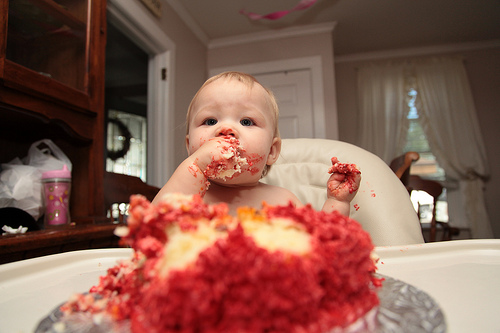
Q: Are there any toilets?
A: No, there are no toilets.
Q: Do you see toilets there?
A: No, there are no toilets.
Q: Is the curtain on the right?
A: Yes, the curtain is on the right of the image.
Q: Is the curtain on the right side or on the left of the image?
A: The curtain is on the right of the image.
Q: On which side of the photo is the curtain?
A: The curtain is on the right of the image.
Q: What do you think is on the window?
A: The curtain is on the window.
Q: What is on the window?
A: The curtain is on the window.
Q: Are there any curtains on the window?
A: Yes, there is a curtain on the window.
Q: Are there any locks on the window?
A: No, there is a curtain on the window.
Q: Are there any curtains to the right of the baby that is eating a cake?
A: Yes, there is a curtain to the right of the baby.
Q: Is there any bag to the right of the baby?
A: No, there is a curtain to the right of the baby.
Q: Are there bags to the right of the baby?
A: No, there is a curtain to the right of the baby.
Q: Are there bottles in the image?
A: Yes, there is a bottle.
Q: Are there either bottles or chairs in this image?
A: Yes, there is a bottle.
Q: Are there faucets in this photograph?
A: No, there are no faucets.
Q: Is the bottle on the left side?
A: Yes, the bottle is on the left of the image.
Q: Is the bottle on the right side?
A: No, the bottle is on the left of the image.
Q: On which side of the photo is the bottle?
A: The bottle is on the left of the image.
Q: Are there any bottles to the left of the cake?
A: Yes, there is a bottle to the left of the cake.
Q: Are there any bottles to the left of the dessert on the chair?
A: Yes, there is a bottle to the left of the cake.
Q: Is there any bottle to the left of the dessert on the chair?
A: Yes, there is a bottle to the left of the cake.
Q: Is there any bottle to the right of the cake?
A: No, the bottle is to the left of the cake.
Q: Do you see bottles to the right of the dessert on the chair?
A: No, the bottle is to the left of the cake.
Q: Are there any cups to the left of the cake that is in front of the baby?
A: No, there is a bottle to the left of the cake.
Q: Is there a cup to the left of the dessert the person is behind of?
A: No, there is a bottle to the left of the cake.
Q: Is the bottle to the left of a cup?
A: No, the bottle is to the left of the cake.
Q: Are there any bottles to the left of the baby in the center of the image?
A: Yes, there is a bottle to the left of the baby.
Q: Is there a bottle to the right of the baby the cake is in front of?
A: No, the bottle is to the left of the baby.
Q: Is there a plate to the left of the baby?
A: No, there is a bottle to the left of the baby.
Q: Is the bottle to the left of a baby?
A: Yes, the bottle is to the left of a baby.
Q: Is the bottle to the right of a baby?
A: No, the bottle is to the left of a baby.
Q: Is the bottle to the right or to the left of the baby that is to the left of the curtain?
A: The bottle is to the left of the baby.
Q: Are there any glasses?
A: No, there are no glasses.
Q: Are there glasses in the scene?
A: No, there are no glasses.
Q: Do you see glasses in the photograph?
A: No, there are no glasses.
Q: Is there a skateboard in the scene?
A: No, there are no skateboards.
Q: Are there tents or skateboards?
A: No, there are no skateboards or tents.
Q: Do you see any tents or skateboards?
A: No, there are no skateboards or tents.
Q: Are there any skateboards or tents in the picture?
A: No, there are no skateboards or tents.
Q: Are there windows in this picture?
A: Yes, there is a window.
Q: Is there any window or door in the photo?
A: Yes, there is a window.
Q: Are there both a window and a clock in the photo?
A: No, there is a window but no clocks.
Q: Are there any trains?
A: No, there are no trains.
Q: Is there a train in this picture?
A: No, there are no trains.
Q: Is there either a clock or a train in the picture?
A: No, there are no trains or clocks.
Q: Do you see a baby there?
A: Yes, there is a baby.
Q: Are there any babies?
A: Yes, there is a baby.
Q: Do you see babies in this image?
A: Yes, there is a baby.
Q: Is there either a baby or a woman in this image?
A: Yes, there is a baby.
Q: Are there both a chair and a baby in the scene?
A: Yes, there are both a baby and a chair.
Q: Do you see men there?
A: No, there are no men.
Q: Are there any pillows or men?
A: No, there are no men or pillows.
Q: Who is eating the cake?
A: The baby is eating the cake.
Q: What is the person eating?
A: The baby is eating a cake.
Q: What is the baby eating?
A: The baby is eating a cake.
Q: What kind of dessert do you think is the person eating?
A: The baby is eating a cake.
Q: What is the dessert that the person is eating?
A: The dessert is a cake.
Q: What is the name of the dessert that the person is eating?
A: The dessert is a cake.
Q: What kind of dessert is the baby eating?
A: The baby is eating a cake.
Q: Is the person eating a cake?
A: Yes, the baby is eating a cake.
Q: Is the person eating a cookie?
A: No, the baby is eating a cake.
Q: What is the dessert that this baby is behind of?
A: The dessert is a cake.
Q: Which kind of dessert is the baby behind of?
A: The baby is behind the cake.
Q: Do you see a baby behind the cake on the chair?
A: Yes, there is a baby behind the cake.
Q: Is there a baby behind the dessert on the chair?
A: Yes, there is a baby behind the cake.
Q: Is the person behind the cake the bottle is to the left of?
A: Yes, the baby is behind the cake.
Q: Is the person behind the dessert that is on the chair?
A: Yes, the baby is behind the cake.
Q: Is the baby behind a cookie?
A: No, the baby is behind the cake.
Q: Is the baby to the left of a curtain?
A: Yes, the baby is to the left of a curtain.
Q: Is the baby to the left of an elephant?
A: No, the baby is to the left of a curtain.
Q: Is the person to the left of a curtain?
A: Yes, the baby is to the left of a curtain.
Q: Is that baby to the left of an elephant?
A: No, the baby is to the left of a curtain.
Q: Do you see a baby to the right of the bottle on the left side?
A: Yes, there is a baby to the right of the bottle.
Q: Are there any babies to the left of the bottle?
A: No, the baby is to the right of the bottle.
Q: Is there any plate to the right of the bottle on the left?
A: No, there is a baby to the right of the bottle.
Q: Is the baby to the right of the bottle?
A: Yes, the baby is to the right of the bottle.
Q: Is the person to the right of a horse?
A: No, the baby is to the right of the bottle.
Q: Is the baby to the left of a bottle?
A: No, the baby is to the right of a bottle.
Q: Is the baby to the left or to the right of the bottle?
A: The baby is to the right of the bottle.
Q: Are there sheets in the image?
A: No, there are no sheets.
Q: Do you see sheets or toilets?
A: No, there are no sheets or toilets.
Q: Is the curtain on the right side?
A: Yes, the curtain is on the right of the image.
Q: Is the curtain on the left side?
A: No, the curtain is on the right of the image.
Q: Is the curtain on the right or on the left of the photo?
A: The curtain is on the right of the image.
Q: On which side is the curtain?
A: The curtain is on the right of the image.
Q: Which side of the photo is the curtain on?
A: The curtain is on the right of the image.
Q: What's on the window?
A: The curtain is on the window.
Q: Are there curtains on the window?
A: Yes, there is a curtain on the window.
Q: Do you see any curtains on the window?
A: Yes, there is a curtain on the window.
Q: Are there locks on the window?
A: No, there is a curtain on the window.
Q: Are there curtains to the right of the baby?
A: Yes, there is a curtain to the right of the baby.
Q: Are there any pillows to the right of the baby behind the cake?
A: No, there is a curtain to the right of the baby.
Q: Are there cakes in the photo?
A: Yes, there is a cake.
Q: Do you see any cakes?
A: Yes, there is a cake.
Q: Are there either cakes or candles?
A: Yes, there is a cake.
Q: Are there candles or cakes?
A: Yes, there is a cake.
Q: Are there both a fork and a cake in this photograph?
A: No, there is a cake but no forks.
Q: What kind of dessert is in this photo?
A: The dessert is a cake.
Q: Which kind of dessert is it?
A: The dessert is a cake.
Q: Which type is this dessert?
A: This is a cake.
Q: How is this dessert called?
A: This is a cake.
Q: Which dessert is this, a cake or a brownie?
A: This is a cake.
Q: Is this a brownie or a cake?
A: This is a cake.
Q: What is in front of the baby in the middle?
A: The cake is in front of the baby.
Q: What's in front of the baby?
A: The cake is in front of the baby.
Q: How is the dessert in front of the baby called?
A: The dessert is a cake.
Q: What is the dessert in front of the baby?
A: The dessert is a cake.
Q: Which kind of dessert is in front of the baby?
A: The dessert is a cake.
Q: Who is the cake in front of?
A: The cake is in front of the baby.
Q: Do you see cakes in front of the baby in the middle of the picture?
A: Yes, there is a cake in front of the baby.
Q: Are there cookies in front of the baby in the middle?
A: No, there is a cake in front of the baby.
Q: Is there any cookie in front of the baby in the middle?
A: No, there is a cake in front of the baby.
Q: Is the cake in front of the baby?
A: Yes, the cake is in front of the baby.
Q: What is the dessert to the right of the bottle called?
A: The dessert is a cake.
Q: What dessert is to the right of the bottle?
A: The dessert is a cake.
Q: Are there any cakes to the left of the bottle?
A: No, the cake is to the right of the bottle.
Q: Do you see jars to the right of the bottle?
A: No, there is a cake to the right of the bottle.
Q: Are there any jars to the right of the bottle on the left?
A: No, there is a cake to the right of the bottle.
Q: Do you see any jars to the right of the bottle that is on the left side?
A: No, there is a cake to the right of the bottle.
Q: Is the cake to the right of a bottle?
A: Yes, the cake is to the right of a bottle.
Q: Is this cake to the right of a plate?
A: No, the cake is to the right of a bottle.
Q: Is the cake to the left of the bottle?
A: No, the cake is to the right of the bottle.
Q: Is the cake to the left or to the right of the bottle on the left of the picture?
A: The cake is to the right of the bottle.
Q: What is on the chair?
A: The cake is on the chair.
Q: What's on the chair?
A: The cake is on the chair.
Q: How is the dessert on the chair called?
A: The dessert is a cake.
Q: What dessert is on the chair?
A: The dessert is a cake.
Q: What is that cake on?
A: The cake is on the chair.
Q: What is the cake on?
A: The cake is on the chair.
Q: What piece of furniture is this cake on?
A: The cake is on the chair.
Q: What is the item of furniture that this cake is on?
A: The piece of furniture is a chair.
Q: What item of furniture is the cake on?
A: The cake is on the chair.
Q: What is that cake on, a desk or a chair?
A: The cake is on a chair.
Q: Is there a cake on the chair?
A: Yes, there is a cake on the chair.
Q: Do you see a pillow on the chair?
A: No, there is a cake on the chair.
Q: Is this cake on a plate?
A: No, the cake is on the chair.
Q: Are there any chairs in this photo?
A: Yes, there is a chair.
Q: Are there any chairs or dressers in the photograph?
A: Yes, there is a chair.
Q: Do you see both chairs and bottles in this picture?
A: Yes, there are both a chair and a bottle.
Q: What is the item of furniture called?
A: The piece of furniture is a chair.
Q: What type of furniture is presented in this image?
A: The furniture is a chair.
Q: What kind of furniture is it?
A: The piece of furniture is a chair.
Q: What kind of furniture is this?
A: This is a chair.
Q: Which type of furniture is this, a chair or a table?
A: This is a chair.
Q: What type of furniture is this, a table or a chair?
A: This is a chair.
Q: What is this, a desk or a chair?
A: This is a chair.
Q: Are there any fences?
A: No, there are no fences.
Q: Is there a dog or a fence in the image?
A: No, there are no fences or dogs.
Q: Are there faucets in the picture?
A: No, there are no faucets.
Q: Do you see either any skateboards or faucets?
A: No, there are no faucets or skateboards.